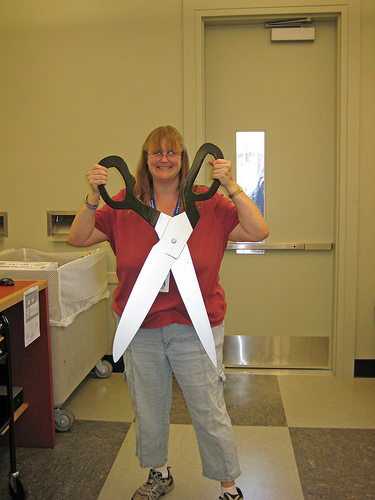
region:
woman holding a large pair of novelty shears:
[54, 114, 279, 494]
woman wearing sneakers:
[123, 467, 243, 493]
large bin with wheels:
[0, 238, 115, 433]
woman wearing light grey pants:
[106, 309, 241, 474]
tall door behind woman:
[174, 0, 349, 375]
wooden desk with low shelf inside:
[0, 279, 54, 446]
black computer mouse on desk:
[0, 275, 16, 290]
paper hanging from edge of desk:
[15, 281, 45, 350]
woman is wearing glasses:
[136, 144, 184, 161]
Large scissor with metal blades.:
[94, 138, 224, 367]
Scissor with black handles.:
[94, 141, 219, 368]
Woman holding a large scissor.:
[68, 123, 268, 498]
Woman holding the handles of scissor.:
[66, 124, 268, 498]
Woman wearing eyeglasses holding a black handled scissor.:
[66, 125, 267, 497]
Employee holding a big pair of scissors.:
[65, 124, 269, 393]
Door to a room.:
[202, 70, 341, 371]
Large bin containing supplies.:
[3, 245, 113, 430]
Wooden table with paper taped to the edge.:
[1, 276, 53, 498]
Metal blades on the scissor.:
[112, 233, 219, 366]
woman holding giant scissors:
[105, 112, 271, 478]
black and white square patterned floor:
[246, 371, 362, 462]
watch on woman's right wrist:
[218, 180, 255, 207]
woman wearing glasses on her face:
[70, 121, 281, 374]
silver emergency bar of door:
[221, 231, 360, 260]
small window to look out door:
[227, 96, 281, 243]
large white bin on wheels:
[8, 228, 121, 439]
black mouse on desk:
[3, 270, 19, 291]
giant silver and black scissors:
[88, 132, 231, 371]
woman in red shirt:
[61, 129, 273, 344]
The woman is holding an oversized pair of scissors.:
[62, 116, 275, 482]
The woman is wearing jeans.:
[105, 288, 244, 470]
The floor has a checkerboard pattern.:
[51, 360, 360, 491]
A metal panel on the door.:
[216, 330, 328, 365]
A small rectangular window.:
[227, 128, 263, 236]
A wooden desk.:
[0, 273, 45, 457]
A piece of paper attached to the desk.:
[11, 276, 44, 352]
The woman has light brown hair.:
[124, 120, 193, 198]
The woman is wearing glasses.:
[139, 130, 178, 176]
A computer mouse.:
[0, 259, 15, 293]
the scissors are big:
[87, 134, 236, 382]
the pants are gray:
[116, 322, 265, 498]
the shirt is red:
[77, 180, 249, 335]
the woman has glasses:
[139, 132, 192, 184]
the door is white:
[198, 10, 372, 379]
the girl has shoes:
[106, 453, 262, 496]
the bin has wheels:
[38, 311, 127, 443]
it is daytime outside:
[237, 135, 261, 192]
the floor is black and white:
[265, 390, 365, 486]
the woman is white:
[62, 118, 272, 325]